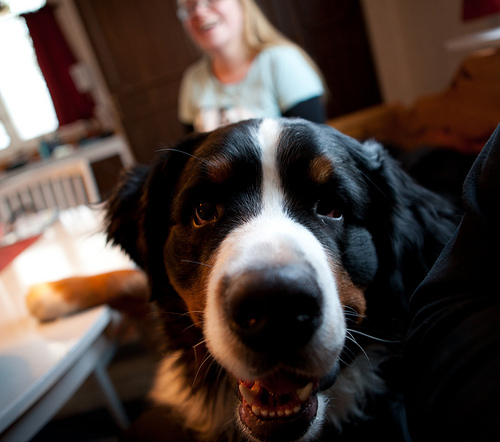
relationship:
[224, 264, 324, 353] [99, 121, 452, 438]
nose on dog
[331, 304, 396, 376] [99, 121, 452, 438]
whiskers on dog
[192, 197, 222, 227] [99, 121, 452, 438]
eye on dog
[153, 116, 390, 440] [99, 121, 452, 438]
head of dog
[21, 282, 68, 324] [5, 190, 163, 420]
paw on table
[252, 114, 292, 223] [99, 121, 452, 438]
stripe on dog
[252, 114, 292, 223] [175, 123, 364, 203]
stripe on forehead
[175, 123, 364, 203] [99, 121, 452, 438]
forehead of dog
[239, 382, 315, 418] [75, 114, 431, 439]
canine tooth of dog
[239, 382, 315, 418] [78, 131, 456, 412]
canine tooth of dog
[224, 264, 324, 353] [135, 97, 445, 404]
nose of dog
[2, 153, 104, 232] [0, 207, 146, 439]
chair by table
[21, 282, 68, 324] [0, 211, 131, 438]
paw on table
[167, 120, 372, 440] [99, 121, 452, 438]
face of dog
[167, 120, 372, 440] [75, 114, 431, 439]
face of dog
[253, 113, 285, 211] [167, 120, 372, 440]
line on face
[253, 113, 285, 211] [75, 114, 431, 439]
line on dog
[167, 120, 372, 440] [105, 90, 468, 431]
face on dog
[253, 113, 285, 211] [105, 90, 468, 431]
line on dog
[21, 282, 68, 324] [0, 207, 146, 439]
paw on table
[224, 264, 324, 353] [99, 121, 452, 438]
nose of dog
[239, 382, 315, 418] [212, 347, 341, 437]
canine tooth in mouth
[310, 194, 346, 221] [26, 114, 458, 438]
eye of dog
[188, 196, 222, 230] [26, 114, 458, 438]
eye of dog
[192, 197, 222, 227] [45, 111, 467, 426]
eye of dog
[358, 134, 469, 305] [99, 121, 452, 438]
ear of dog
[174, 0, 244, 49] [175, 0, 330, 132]
face of lady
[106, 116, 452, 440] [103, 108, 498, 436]
head of dog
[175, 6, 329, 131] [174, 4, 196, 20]
lady wearing glasses